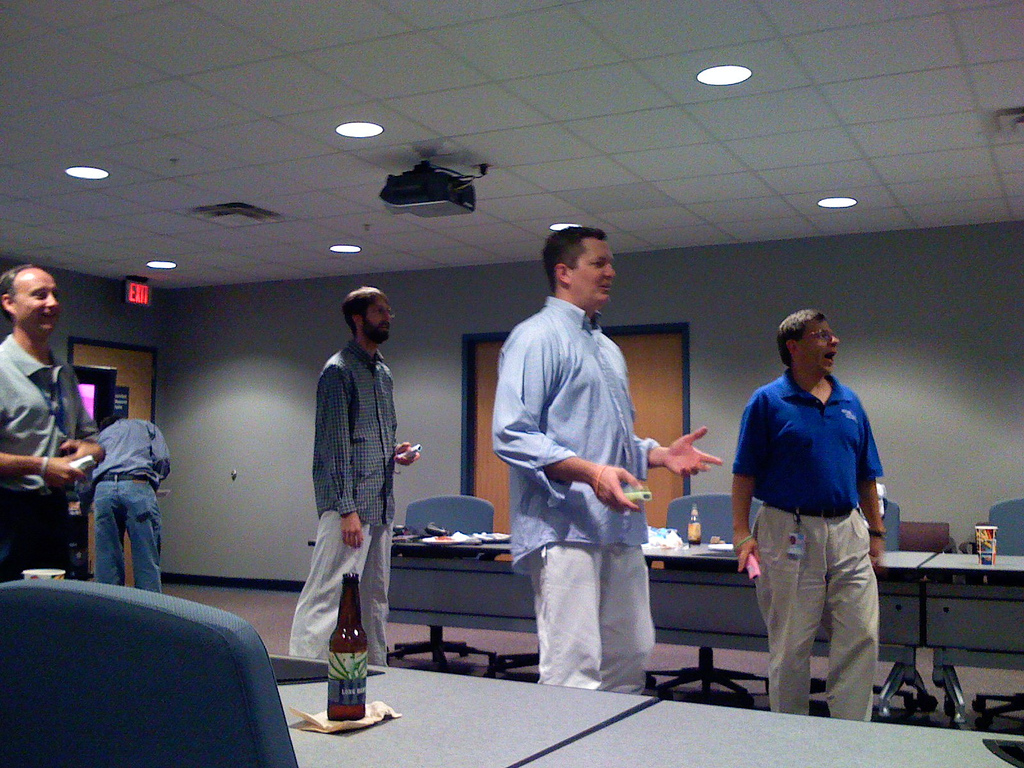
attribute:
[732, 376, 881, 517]
shirt — dark blue, collar shirt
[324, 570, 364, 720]
bottle — brown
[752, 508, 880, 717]
pants — khaki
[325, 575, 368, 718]
bottle — brown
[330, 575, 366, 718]
bottle — brown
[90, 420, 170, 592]
man — closest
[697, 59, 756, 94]
light — small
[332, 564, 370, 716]
bottle — tall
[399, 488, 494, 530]
chair — blue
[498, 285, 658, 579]
shirt — blue, long sleeve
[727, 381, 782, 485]
sleeve — short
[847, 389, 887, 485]
sleeve — short